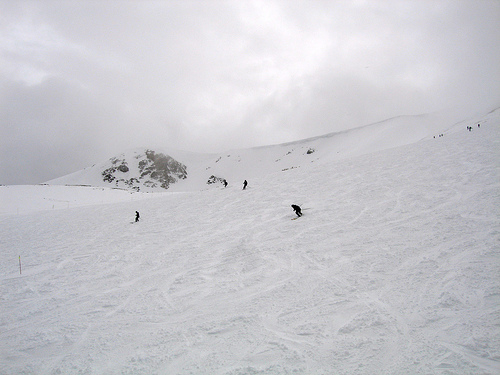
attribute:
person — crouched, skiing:
[289, 200, 306, 220]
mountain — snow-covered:
[131, 154, 191, 186]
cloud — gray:
[221, 31, 276, 64]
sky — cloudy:
[14, 4, 484, 95]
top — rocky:
[124, 146, 166, 158]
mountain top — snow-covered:
[385, 116, 494, 148]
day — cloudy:
[25, 6, 469, 96]